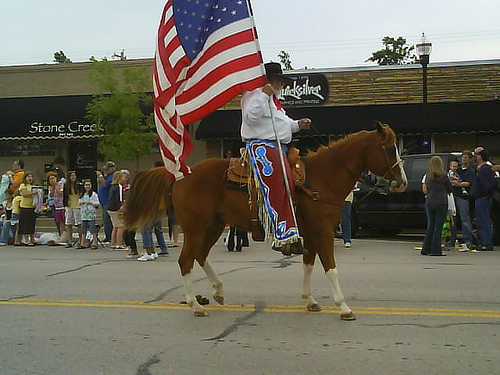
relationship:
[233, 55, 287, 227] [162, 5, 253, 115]
man carrying flag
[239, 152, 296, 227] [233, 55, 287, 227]
pants of man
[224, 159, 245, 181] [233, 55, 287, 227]
saddle of man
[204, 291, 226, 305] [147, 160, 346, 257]
hooves of horse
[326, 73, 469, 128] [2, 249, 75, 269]
store fronts facing street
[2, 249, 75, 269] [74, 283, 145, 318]
street has lines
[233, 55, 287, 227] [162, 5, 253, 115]
man holding flag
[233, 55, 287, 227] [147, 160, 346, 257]
man riding horse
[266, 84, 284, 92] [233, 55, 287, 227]
facial hair on man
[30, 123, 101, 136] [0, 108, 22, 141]
stone creek on awning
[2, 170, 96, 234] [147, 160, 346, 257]
audience watching horse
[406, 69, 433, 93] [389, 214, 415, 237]
light behind car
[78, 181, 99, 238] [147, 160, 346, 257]
girl watching horse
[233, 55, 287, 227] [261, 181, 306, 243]
man wearing chaps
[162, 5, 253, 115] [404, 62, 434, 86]
flag on pole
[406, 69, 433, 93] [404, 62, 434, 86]
light on pole